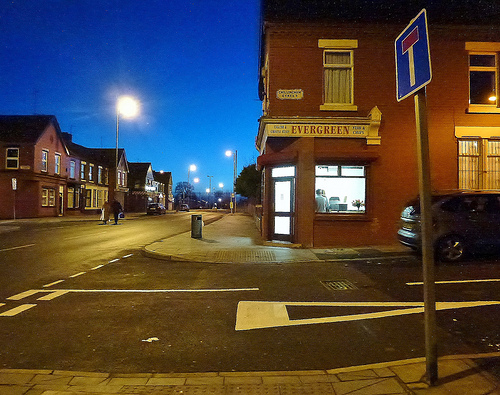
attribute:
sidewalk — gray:
[1, 351, 499, 393]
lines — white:
[231, 290, 498, 328]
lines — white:
[434, 271, 499, 288]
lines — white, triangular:
[230, 292, 498, 332]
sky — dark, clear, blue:
[44, 7, 239, 134]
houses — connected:
[4, 109, 199, 217]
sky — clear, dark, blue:
[53, 19, 195, 70]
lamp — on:
[114, 92, 140, 125]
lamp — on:
[188, 162, 197, 172]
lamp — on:
[216, 182, 223, 189]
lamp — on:
[223, 148, 231, 158]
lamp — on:
[190, 175, 199, 183]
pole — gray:
[389, 90, 466, 389]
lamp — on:
[220, 146, 240, 168]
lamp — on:
[215, 177, 225, 191]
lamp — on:
[185, 158, 197, 175]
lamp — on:
[192, 177, 201, 185]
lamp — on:
[109, 86, 140, 121]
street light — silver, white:
[101, 85, 253, 215]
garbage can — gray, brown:
[191, 215, 203, 240]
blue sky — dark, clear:
[1, 0, 263, 198]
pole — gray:
[409, 93, 451, 386]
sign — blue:
[392, 7, 432, 103]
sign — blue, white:
[385, 4, 437, 107]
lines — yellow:
[0, 237, 40, 253]